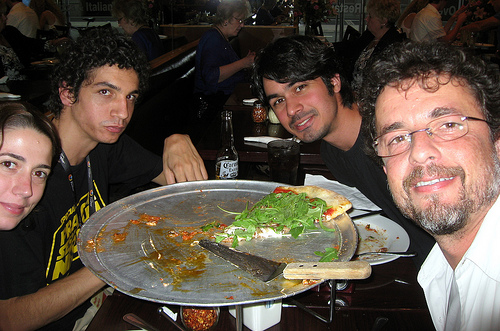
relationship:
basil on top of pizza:
[236, 203, 294, 242] [235, 175, 338, 239]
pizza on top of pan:
[235, 175, 338, 239] [88, 174, 342, 307]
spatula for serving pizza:
[203, 248, 374, 291] [235, 175, 338, 239]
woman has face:
[1, 114, 56, 224] [0, 140, 41, 236]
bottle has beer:
[198, 101, 247, 186] [216, 162, 240, 183]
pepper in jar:
[189, 313, 214, 324] [174, 306, 211, 331]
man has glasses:
[392, 74, 495, 330] [373, 114, 488, 158]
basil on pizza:
[236, 203, 294, 242] [235, 175, 338, 239]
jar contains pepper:
[174, 306, 211, 331] [189, 313, 214, 324]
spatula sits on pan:
[203, 248, 374, 291] [88, 174, 342, 307]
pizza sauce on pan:
[111, 196, 214, 284] [88, 174, 342, 307]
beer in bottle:
[216, 162, 240, 183] [198, 101, 247, 186]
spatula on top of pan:
[203, 248, 374, 291] [88, 174, 342, 307]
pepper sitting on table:
[183, 308, 214, 330] [89, 166, 397, 329]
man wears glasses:
[392, 74, 495, 330] [373, 114, 488, 158]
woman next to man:
[1, 114, 56, 224] [16, 41, 198, 331]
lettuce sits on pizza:
[224, 190, 313, 233] [235, 175, 338, 239]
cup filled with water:
[265, 139, 305, 186] [274, 150, 296, 182]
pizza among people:
[235, 175, 338, 239] [18, 57, 496, 328]